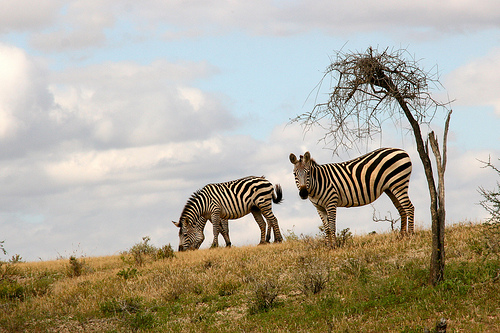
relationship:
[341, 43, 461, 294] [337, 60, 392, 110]
tree has branches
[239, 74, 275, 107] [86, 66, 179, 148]
sky has clouds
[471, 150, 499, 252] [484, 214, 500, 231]
bush has branches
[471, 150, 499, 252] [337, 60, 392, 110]
bush has branches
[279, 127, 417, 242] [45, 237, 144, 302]
zebra on hill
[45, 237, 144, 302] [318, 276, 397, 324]
hill has grass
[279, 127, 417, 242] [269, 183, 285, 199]
zebra has tail